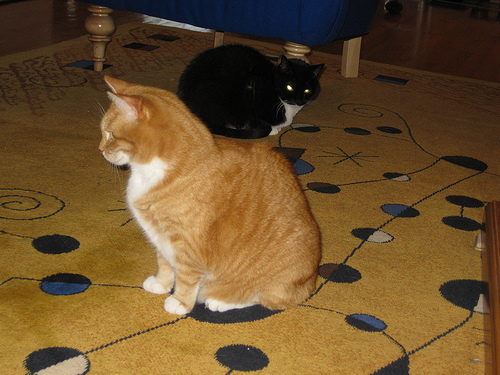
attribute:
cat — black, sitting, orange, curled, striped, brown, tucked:
[178, 44, 313, 140]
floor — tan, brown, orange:
[424, 98, 475, 128]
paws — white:
[127, 276, 189, 315]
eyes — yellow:
[275, 80, 314, 95]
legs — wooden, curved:
[71, 10, 117, 70]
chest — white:
[117, 187, 162, 252]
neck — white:
[272, 108, 307, 119]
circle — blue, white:
[308, 174, 335, 200]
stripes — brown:
[215, 190, 252, 227]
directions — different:
[57, 308, 447, 345]